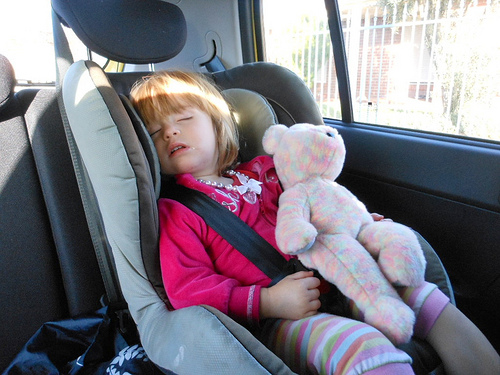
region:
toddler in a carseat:
[0, 3, 490, 370]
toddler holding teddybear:
[256, 113, 461, 339]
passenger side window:
[266, 0, 494, 136]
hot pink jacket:
[141, 166, 341, 316]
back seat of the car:
[0, 61, 106, 372]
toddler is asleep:
[121, 66, 437, 332]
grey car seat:
[53, 55, 456, 370]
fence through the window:
[282, 0, 492, 126]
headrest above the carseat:
[56, 2, 189, 62]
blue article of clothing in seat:
[0, 311, 161, 372]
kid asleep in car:
[134, 68, 459, 369]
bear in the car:
[269, 125, 431, 335]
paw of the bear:
[273, 218, 315, 255]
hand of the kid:
[276, 270, 323, 317]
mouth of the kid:
[162, 140, 196, 161]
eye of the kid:
[173, 111, 200, 125]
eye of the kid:
[153, 126, 166, 140]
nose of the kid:
[164, 126, 179, 140]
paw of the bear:
[381, 252, 421, 293]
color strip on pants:
[345, 343, 395, 370]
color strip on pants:
[343, 338, 387, 363]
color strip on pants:
[331, 332, 376, 372]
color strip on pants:
[328, 320, 365, 371]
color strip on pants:
[318, 320, 354, 363]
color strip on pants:
[312, 320, 346, 368]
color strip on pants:
[308, 320, 339, 363]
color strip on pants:
[413, 291, 448, 331]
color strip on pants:
[413, 281, 433, 311]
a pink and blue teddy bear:
[260, 121, 426, 348]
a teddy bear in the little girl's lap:
[127, 68, 426, 345]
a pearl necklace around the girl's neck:
[195, 169, 263, 192]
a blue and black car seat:
[50, 2, 499, 374]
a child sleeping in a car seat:
[50, 0, 498, 374]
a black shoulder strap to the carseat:
[157, 180, 307, 286]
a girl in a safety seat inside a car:
[51, 0, 498, 372]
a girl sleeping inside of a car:
[1, 0, 498, 373]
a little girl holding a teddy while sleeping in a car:
[2, 1, 497, 372]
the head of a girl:
[141, 66, 253, 173]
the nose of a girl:
[153, 124, 186, 147]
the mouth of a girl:
[157, 120, 229, 167]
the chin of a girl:
[148, 126, 240, 182]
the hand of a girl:
[247, 251, 347, 325]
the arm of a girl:
[156, 203, 273, 315]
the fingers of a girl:
[283, 259, 333, 314]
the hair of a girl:
[129, 75, 258, 156]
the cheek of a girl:
[176, 115, 234, 166]